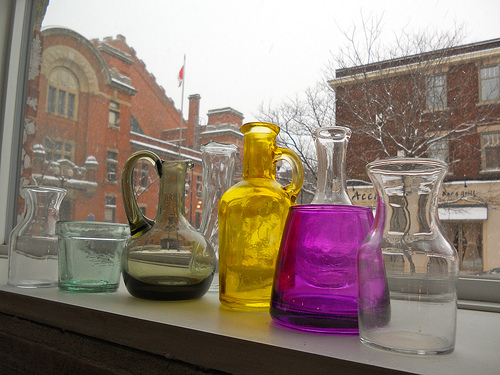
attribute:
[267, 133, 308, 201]
handle — amber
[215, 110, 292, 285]
pitcher — glass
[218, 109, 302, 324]
bottle — glass, yellow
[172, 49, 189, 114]
flag — red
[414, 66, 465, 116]
window — curtained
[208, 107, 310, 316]
bottle — yellow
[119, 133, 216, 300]
pitcher — green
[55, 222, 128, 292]
jar — clear, glass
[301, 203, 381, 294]
vase — clear, glass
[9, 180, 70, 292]
carafe — clear, glass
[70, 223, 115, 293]
planter — light green, glass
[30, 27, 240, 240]
red building — brick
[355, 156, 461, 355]
vase — clear, glass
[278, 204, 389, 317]
vase — clear, purple, glass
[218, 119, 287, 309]
vase — clear, yellow, colorful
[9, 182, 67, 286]
vase — clear, glass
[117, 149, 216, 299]
vase — clear, green, glass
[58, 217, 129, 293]
vase — aqua, glass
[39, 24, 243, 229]
building — brick, old, red, white, storefront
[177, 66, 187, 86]
flag — red, white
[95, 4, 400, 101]
sky — cloudy, overcast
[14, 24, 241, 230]
townhall — red, large, brick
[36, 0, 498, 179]
sky — white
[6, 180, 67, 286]
carafe — smaller, glass, clear, dirty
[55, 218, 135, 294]
holder — green